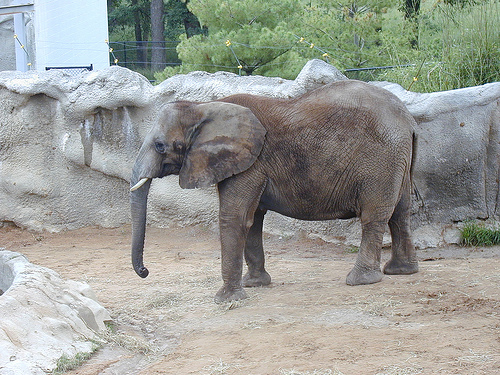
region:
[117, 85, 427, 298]
A large grey elephant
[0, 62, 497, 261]
Grey stone wall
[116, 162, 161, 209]
White elephant tusk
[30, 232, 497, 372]
Dirt and grass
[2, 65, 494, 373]
The inside of an elephant pen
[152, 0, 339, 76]
Green pine needles on a tree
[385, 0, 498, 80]
Some type of shrub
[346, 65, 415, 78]
A metal fence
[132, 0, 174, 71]
Trunk of a pine tree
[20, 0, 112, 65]
A white wall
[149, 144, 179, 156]
the eye is black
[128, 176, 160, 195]
the tusk is short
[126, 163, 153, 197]
the tusk is white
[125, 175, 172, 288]
the trunk is gray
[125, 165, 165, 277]
tusk is on trunk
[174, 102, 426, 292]
the elephant is gray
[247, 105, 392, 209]
the elephant is wrinkled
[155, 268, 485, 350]
the water is brown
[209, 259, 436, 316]
four hooves in water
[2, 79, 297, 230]
the wall is rock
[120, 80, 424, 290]
grey elephant in enclosure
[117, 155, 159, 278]
trunk of grey elephant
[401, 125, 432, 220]
tail of grey elephant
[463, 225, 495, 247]
patch of green grass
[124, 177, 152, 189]
ivory tusk of elephant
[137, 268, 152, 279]
opening of elephant trunk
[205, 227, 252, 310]
leg of grey elephant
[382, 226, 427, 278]
leg of grey elephant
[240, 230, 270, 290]
leg of grey elephant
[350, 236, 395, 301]
leg of grey elephant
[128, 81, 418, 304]
a large grey elephant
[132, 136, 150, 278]
a long elephant trunk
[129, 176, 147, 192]
a short white tusk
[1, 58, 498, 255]
a tall rock wall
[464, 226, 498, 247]
a small patch of grass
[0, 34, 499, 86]
electrical wires on top of rock wall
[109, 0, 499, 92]
trees and bushes in the background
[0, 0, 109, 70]
a white building in the background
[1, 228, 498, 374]
dirt on the ground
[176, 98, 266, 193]
a big grey elephant ear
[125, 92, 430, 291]
A gray elephant.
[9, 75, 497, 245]
A gray stone wall.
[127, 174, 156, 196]
A white elephant tusk.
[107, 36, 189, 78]
A black chain link fence.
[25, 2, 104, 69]
A white building.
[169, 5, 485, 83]
Green trees behind a fence.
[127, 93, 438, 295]
A animal in a zoo.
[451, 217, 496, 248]
Green grass growing on a wall.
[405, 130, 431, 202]
A elephant tail.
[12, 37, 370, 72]
Barb wire on a fence.